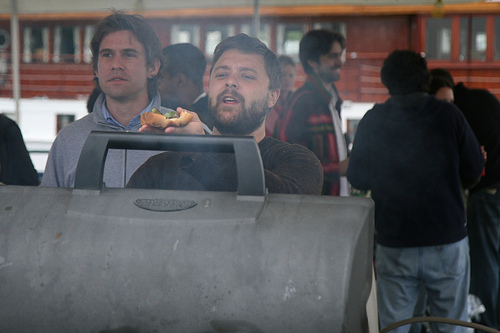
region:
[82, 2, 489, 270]
people are standing around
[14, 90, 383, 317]
the grill is open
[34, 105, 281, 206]
the handle is black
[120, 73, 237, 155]
the man is holding bread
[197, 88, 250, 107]
the mouth is open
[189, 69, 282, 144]
the man has a beard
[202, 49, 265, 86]
the eyes are squinted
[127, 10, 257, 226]
smoke is coming from the grill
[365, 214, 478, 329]
the man is wearing jeans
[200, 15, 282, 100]
the hair is brown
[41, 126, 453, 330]
black smoker grill in front of picture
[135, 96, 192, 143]
sandwich in man's hand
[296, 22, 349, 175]
man in red plaid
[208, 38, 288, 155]
man with brown beard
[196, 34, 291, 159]
man with brown mustache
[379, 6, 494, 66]
red side of building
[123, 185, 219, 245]
emblem in center of grill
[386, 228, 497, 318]
man wearing blue jeans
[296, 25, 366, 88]
man smiling in background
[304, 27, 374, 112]
man with dark beard on face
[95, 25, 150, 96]
the head of the person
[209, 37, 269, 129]
the head of the person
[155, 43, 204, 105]
the head of the person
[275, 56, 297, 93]
the head of the person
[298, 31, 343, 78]
the head of the person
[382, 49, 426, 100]
the head of the person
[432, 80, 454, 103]
the head of the person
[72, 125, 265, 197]
the large handle of the BBQ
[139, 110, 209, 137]
the hand of the man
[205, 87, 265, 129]
the beard of the face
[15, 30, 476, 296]
this is outside a building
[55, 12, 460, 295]
this is under a shelter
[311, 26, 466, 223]
these men are socializing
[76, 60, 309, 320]
these men are cooking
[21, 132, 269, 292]
this is a grill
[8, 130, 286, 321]
the grill is cooking the food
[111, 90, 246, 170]
the man is holding food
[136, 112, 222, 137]
the man has a bun in his hand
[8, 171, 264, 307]
the grill is made of metal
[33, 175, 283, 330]
the grill is dark gray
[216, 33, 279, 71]
Man has brown hair.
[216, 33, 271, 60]
Man has short hair.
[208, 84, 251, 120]
Man has brown facial hair.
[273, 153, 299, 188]
Man wearing dark sweater.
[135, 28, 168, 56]
Man has brown hair.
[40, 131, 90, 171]
Man wearing gray shirt.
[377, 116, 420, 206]
Man wearing black sweatshirt.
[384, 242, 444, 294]
Man wearing blue jeans.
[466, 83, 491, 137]
Man wearing black shirt.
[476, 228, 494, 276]
Man wearing dark pants.